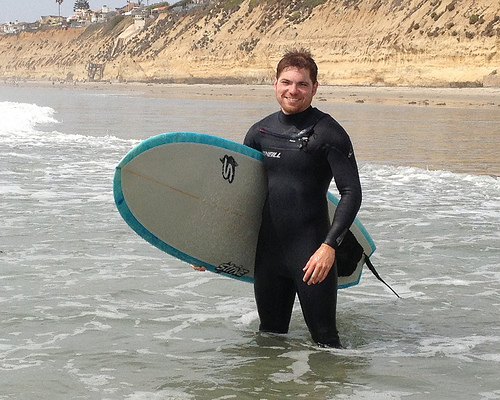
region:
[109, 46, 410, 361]
A man holding a surfboard ready to surf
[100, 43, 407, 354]
A man holding a surfboard ready to surf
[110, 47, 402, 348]
A man holding a surfboard ready to surf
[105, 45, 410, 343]
A man holding a surfboard ready to surf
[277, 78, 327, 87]
Man has dark eyebrows.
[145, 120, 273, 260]
Surfboard is blue and white.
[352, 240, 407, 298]
Black cord attached to board.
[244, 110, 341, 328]
Man's wet suit is black.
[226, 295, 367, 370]
Man is knee deep in water.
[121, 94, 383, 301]
man holding a surf board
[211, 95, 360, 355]
Man wearing a wet suit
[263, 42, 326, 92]
man with brown hair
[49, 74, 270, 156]
water washing up ashore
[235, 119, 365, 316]
person wearing a black wetsuit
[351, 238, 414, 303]
strap on a surf board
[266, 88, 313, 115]
man wearing a beard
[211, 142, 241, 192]
sticker on a surf board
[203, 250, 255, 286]
logo on a surf board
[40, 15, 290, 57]
mountains near the ocean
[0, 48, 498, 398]
Man standing in water holding a surfboard.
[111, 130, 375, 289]
A blue and white surfboard.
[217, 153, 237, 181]
Black and white insignia on the surfboard.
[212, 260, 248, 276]
Black and white letters on the edge of the board.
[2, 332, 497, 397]
The water is up to the man's knees.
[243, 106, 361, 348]
A black wetsuit on the man.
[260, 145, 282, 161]
White letters on the front of the wetsuit.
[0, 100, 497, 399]
Foam on the surface of the water.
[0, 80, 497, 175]
A sandy beach.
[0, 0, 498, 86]
A sandy hillside along the beach.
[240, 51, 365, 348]
A man standing in water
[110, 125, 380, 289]
Blue and white surfboard being carried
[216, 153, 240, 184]
"S" logo on a surf board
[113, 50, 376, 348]
Smiling man standing in the water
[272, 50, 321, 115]
A smiling man's face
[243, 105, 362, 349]
A black, skin-tight swim suit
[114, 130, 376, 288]
Blue and white surfboard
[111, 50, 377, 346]
Surfer in a black suit with his board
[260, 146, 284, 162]
Logo on the front of a black swim suit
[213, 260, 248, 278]
"STINE" logo on a surf board